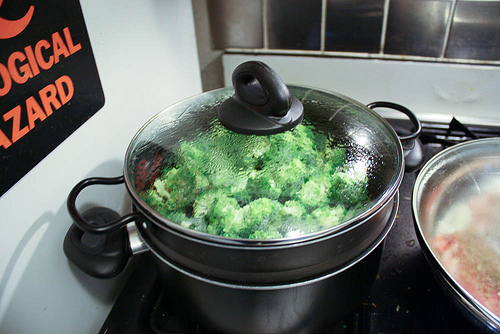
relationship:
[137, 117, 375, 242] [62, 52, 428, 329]
broccoli in double boiler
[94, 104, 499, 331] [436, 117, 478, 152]
range top has control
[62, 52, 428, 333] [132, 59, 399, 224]
double boiler has lid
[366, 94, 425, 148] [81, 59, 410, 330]
handle on a pot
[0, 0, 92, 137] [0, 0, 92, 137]
letter on a letter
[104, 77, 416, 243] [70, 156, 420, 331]
pot lid on a pot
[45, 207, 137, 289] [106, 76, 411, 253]
handle on a lid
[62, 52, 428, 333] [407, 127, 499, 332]
double boiler under another fry pan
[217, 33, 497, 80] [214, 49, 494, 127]
trim on a wall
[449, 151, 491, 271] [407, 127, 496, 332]
glass on fry pan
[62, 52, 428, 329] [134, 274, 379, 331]
double boiler on burner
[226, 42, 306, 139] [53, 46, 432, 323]
handle on pot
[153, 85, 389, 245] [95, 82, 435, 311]
glass lid on pot